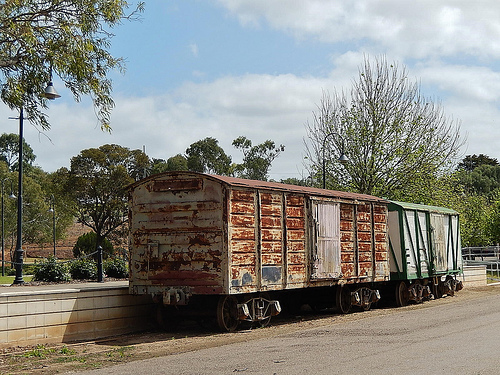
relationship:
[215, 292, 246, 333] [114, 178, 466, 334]
wheel of a train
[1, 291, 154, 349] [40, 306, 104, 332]
wall made of bricks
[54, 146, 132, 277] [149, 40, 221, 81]
tree in distance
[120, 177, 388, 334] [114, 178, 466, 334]
box car from train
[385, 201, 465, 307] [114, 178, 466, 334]
new box car from train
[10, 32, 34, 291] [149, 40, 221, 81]
streetlight in distance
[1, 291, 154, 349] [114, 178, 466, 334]
wall by train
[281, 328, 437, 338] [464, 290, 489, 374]
chain marking path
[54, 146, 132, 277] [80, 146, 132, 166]
tree with a top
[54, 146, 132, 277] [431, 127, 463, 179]
tree with hanging branches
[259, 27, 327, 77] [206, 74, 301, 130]
sky with partly clouds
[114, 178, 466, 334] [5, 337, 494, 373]
train by road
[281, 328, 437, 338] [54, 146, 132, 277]
chain separates tree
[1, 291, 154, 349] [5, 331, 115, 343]
wall rusted bottom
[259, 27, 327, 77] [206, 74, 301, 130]
sky with clouds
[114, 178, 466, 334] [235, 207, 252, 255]
train that rust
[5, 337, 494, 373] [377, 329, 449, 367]
road with litter free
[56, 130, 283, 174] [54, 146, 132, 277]
row of tree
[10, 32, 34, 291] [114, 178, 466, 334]
streetlight with train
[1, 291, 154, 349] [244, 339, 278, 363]
wall with dirt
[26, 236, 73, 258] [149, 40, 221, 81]
fevce with distance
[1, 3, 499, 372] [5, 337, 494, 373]
sceme outdoors road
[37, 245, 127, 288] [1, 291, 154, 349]
bushes mear wall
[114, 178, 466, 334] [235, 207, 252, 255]
train with a lot rust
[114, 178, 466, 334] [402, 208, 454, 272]
train with greem am white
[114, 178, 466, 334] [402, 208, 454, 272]
train parked greem am white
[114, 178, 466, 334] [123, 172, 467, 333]
train with two train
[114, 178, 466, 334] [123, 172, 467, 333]
train parked train